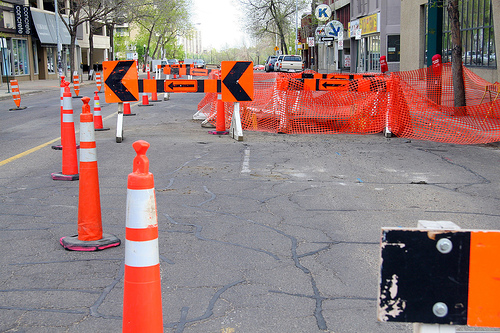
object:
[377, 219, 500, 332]
sign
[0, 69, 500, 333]
road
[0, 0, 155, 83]
businesses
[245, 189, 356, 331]
lines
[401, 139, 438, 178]
ground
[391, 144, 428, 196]
ground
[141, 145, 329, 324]
cracks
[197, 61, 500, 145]
fencing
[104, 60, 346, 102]
arrows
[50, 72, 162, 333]
road sign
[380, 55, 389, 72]
bags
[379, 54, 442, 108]
meters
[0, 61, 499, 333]
city street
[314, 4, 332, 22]
signs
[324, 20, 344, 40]
signs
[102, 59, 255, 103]
white light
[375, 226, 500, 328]
banner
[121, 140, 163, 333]
cone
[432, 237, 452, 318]
bolts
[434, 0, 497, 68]
windows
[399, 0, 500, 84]
building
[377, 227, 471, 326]
end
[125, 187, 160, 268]
stripes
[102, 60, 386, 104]
signs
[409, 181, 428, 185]
hole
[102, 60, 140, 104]
detour sign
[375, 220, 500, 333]
barrier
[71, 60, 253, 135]
sign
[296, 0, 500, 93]
businesses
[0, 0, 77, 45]
side